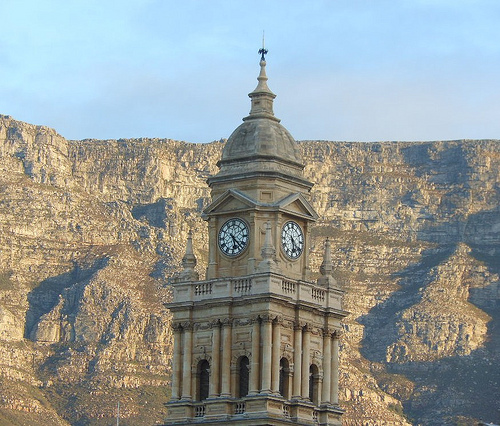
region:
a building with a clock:
[132, 30, 387, 425]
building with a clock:
[158, 37, 386, 413]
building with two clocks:
[91, 39, 355, 423]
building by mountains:
[79, 41, 444, 424]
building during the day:
[116, 39, 423, 424]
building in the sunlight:
[108, 38, 421, 413]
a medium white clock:
[209, 217, 271, 279]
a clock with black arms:
[212, 219, 260, 288]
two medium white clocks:
[179, 210, 327, 270]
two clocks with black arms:
[198, 215, 310, 268]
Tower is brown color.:
[197, 136, 335, 418]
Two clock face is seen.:
[210, 215, 315, 252]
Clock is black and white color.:
[221, 215, 316, 255]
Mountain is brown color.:
[363, 243, 480, 416]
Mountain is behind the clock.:
[23, 125, 487, 397]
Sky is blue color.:
[27, 21, 239, 122]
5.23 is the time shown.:
[215, 213, 304, 263]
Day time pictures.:
[48, 36, 449, 422]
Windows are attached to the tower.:
[192, 350, 327, 410]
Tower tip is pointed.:
[242, 31, 284, 111]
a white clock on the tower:
[213, 217, 251, 261]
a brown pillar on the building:
[246, 315, 287, 400]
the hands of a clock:
[226, 230, 245, 252]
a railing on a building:
[172, 269, 347, 321]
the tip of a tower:
[241, 23, 278, 121]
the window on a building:
[226, 349, 253, 402]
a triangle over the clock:
[198, 187, 259, 224]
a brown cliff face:
[0, 112, 498, 423]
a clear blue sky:
[0, 0, 499, 143]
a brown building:
[155, 22, 350, 424]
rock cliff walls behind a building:
[2, 113, 495, 424]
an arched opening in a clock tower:
[233, 349, 256, 411]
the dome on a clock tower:
[214, 112, 315, 171]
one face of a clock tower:
[214, 209, 256, 263]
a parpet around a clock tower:
[170, 269, 353, 310]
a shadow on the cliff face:
[21, 244, 114, 338]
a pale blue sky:
[9, 11, 493, 129]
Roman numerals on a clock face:
[222, 220, 246, 250]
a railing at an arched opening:
[192, 396, 209, 416]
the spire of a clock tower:
[244, 26, 279, 99]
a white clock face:
[208, 218, 255, 269]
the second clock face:
[277, 217, 313, 256]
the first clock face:
[215, 207, 257, 272]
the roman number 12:
[229, 215, 238, 227]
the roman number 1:
[235, 220, 243, 227]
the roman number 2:
[237, 226, 249, 233]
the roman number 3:
[240, 230, 249, 240]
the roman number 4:
[238, 236, 250, 248]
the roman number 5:
[236, 243, 243, 253]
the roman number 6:
[229, 241, 238, 256]